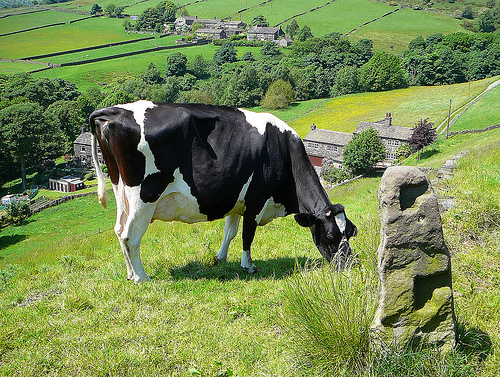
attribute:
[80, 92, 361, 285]
cow — black, white, brown, standing, eating, grazing, multi-colored, mammal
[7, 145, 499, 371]
hill — rolling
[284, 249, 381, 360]
grass — tuft, large, green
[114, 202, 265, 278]
legs — white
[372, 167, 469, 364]
pillar — rock, grey, stone, marker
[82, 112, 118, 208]
tail — black, white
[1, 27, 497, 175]
trees — green, leafy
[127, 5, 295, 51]
houses — small village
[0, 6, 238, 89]
field — green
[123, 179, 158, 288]
leg — hind leg